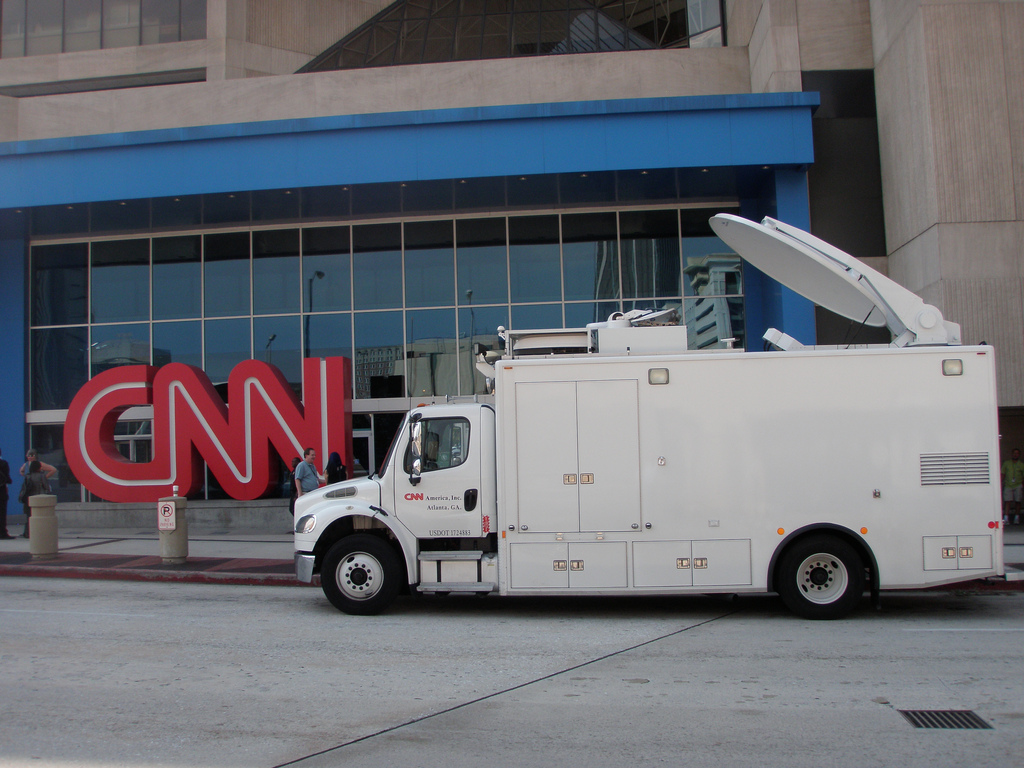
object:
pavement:
[3, 519, 281, 567]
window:
[400, 411, 480, 487]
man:
[286, 436, 325, 503]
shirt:
[288, 467, 316, 496]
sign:
[52, 344, 352, 513]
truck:
[274, 182, 994, 609]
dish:
[702, 195, 976, 337]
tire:
[771, 534, 875, 617]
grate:
[889, 696, 993, 735]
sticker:
[393, 487, 484, 516]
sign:
[146, 493, 179, 537]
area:
[0, 98, 807, 497]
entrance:
[2, 168, 817, 487]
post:
[145, 484, 200, 551]